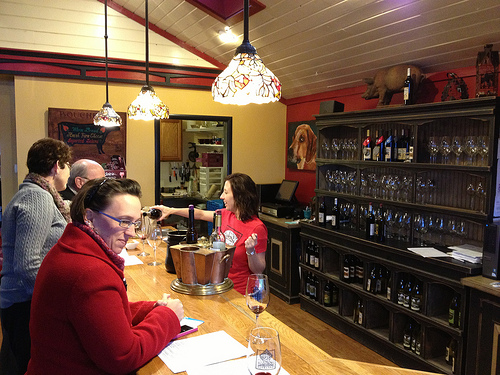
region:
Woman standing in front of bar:
[30, 168, 179, 373]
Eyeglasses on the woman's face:
[87, 206, 143, 238]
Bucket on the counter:
[165, 234, 238, 306]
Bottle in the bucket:
[203, 203, 229, 253]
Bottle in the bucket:
[178, 199, 207, 263]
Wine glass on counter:
[242, 327, 283, 374]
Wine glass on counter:
[239, 266, 275, 353]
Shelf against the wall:
[297, 96, 497, 353]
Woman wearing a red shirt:
[182, 168, 273, 313]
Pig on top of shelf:
[348, 59, 439, 114]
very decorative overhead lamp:
[198, 2, 287, 112]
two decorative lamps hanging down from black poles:
[122, 0, 299, 126]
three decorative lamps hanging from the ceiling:
[88, 1, 285, 133]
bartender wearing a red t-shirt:
[141, 171, 276, 305]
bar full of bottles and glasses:
[297, 99, 497, 373]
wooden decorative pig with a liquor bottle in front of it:
[356, 61, 431, 112]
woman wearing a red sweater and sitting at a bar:
[26, 173, 216, 373]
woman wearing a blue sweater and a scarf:
[1, 128, 73, 317]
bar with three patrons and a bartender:
[0, 19, 499, 373]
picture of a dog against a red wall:
[283, 105, 316, 185]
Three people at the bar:
[3, 133, 185, 365]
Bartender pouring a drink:
[143, 171, 267, 294]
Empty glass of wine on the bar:
[244, 269, 270, 345]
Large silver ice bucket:
[170, 236, 236, 298]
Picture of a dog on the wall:
[286, 119, 318, 174]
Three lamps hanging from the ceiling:
[94, 32, 281, 129]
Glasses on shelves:
[316, 115, 491, 249]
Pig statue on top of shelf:
[362, 61, 425, 103]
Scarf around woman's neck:
[21, 170, 65, 217]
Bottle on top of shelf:
[400, 61, 417, 110]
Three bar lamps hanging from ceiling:
[26, 25, 362, 195]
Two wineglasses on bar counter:
[185, 277, 307, 370]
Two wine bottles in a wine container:
[154, 192, 251, 295]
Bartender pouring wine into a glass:
[132, 126, 278, 288]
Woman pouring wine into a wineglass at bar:
[124, 165, 309, 314]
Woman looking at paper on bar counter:
[6, 143, 298, 372]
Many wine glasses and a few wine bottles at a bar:
[309, 91, 494, 263]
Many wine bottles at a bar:
[266, 210, 481, 372]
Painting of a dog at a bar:
[260, 43, 390, 231]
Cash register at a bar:
[258, 159, 326, 294]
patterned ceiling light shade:
[210, 20, 290, 120]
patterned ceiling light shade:
[91, 95, 136, 132]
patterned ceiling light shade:
[119, 86, 171, 129]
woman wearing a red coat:
[17, 218, 176, 374]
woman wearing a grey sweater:
[0, 176, 75, 300]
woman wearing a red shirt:
[202, 198, 268, 295]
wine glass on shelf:
[379, 206, 473, 256]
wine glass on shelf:
[420, 132, 493, 163]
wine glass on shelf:
[356, 158, 416, 200]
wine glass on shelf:
[311, 157, 370, 199]